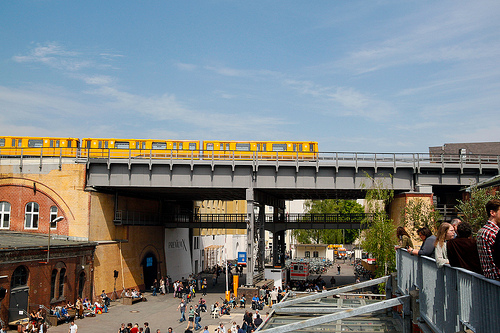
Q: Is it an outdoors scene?
A: Yes, it is outdoors.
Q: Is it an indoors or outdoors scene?
A: It is outdoors.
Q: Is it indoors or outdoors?
A: It is outdoors.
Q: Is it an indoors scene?
A: No, it is outdoors.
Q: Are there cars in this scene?
A: No, there are no cars.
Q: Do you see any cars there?
A: No, there are no cars.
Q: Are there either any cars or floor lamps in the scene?
A: No, there are no cars or floor lamps.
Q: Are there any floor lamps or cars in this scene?
A: No, there are no cars or floor lamps.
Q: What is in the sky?
A: The clouds are in the sky.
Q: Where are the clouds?
A: The clouds are in the sky.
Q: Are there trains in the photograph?
A: Yes, there is a train.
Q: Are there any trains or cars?
A: Yes, there is a train.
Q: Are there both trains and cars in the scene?
A: No, there is a train but no cars.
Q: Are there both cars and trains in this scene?
A: No, there is a train but no cars.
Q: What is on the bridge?
A: The train is on the bridge.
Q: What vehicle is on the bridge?
A: The vehicle is a train.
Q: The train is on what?
A: The train is on the bridge.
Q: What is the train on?
A: The train is on the bridge.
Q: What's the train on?
A: The train is on the bridge.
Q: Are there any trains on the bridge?
A: Yes, there is a train on the bridge.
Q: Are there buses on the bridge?
A: No, there is a train on the bridge.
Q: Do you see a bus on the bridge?
A: No, there is a train on the bridge.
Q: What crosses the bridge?
A: The train crosses the bridge.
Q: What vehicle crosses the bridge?
A: The vehicle is a train.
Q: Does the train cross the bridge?
A: Yes, the train crosses the bridge.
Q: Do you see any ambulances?
A: Yes, there is an ambulance.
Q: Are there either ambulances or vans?
A: Yes, there is an ambulance.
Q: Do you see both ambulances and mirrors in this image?
A: No, there is an ambulance but no mirrors.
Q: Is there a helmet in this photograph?
A: No, there are no helmets.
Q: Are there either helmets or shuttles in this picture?
A: No, there are no helmets or shuttles.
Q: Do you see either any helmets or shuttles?
A: No, there are no helmets or shuttles.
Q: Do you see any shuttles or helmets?
A: No, there are no helmets or shuttles.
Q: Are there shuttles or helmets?
A: No, there are no helmets or shuttles.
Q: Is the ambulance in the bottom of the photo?
A: Yes, the ambulance is in the bottom of the image.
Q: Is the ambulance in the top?
A: No, the ambulance is in the bottom of the image.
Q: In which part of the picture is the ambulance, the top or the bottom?
A: The ambulance is in the bottom of the image.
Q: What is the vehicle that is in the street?
A: The vehicle is an ambulance.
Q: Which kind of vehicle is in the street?
A: The vehicle is an ambulance.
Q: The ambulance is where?
A: The ambulance is in the street.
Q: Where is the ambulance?
A: The ambulance is in the street.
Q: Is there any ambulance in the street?
A: Yes, there is an ambulance in the street.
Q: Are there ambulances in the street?
A: Yes, there is an ambulance in the street.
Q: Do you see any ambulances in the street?
A: Yes, there is an ambulance in the street.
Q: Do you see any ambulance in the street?
A: Yes, there is an ambulance in the street.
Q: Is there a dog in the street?
A: No, there is an ambulance in the street.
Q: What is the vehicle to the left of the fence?
A: The vehicle is an ambulance.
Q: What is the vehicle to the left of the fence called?
A: The vehicle is an ambulance.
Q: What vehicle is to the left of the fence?
A: The vehicle is an ambulance.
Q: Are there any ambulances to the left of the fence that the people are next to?
A: Yes, there is an ambulance to the left of the fence.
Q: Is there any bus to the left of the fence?
A: No, there is an ambulance to the left of the fence.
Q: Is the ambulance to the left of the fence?
A: Yes, the ambulance is to the left of the fence.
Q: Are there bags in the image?
A: No, there are no bags.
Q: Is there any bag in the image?
A: No, there are no bags.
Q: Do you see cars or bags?
A: No, there are no bags or cars.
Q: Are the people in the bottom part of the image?
A: Yes, the people are in the bottom of the image.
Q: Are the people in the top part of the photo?
A: No, the people are in the bottom of the image.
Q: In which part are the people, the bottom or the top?
A: The people are in the bottom of the image.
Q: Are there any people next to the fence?
A: Yes, there are people next to the fence.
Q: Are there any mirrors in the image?
A: No, there are no mirrors.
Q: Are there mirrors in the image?
A: No, there are no mirrors.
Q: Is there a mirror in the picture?
A: No, there are no mirrors.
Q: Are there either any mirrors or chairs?
A: No, there are no mirrors or chairs.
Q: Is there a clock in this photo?
A: No, there are no clocks.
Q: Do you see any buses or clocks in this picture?
A: No, there are no clocks or buses.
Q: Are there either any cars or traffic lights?
A: No, there are no cars or traffic lights.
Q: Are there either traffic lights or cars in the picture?
A: No, there are no cars or traffic lights.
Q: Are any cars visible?
A: No, there are no cars.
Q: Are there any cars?
A: No, there are no cars.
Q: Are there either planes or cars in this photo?
A: No, there are no cars or planes.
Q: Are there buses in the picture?
A: No, there are no buses.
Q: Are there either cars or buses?
A: No, there are no buses or cars.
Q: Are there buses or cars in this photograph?
A: No, there are no buses or cars.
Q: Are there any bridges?
A: Yes, there is a bridge.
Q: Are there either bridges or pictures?
A: Yes, there is a bridge.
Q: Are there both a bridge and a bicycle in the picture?
A: No, there is a bridge but no bicycles.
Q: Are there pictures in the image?
A: No, there are no pictures.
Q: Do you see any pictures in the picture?
A: No, there are no pictures.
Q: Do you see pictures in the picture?
A: No, there are no pictures.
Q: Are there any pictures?
A: No, there are no pictures.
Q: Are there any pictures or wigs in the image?
A: No, there are no pictures or wigs.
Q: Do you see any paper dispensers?
A: No, there are no paper dispensers.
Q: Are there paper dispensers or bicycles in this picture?
A: No, there are no paper dispensers or bicycles.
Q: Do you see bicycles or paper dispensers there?
A: No, there are no paper dispensers or bicycles.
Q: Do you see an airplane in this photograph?
A: No, there are no airplanes.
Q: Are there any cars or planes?
A: No, there are no planes or cars.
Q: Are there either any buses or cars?
A: No, there are no cars or buses.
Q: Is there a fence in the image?
A: Yes, there is a fence.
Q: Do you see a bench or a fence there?
A: Yes, there is a fence.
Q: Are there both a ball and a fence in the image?
A: No, there is a fence but no balls.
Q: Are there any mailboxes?
A: No, there are no mailboxes.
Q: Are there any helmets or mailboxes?
A: No, there are no mailboxes or helmets.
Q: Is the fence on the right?
A: Yes, the fence is on the right of the image.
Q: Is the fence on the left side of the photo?
A: No, the fence is on the right of the image.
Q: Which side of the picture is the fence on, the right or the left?
A: The fence is on the right of the image.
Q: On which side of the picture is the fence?
A: The fence is on the right of the image.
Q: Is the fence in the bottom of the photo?
A: Yes, the fence is in the bottom of the image.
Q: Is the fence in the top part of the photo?
A: No, the fence is in the bottom of the image.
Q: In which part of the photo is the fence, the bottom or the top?
A: The fence is in the bottom of the image.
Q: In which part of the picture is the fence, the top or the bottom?
A: The fence is in the bottom of the image.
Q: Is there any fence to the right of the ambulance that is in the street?
A: Yes, there is a fence to the right of the ambulance.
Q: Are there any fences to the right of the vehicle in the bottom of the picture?
A: Yes, there is a fence to the right of the ambulance.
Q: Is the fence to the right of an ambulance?
A: Yes, the fence is to the right of an ambulance.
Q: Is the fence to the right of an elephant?
A: No, the fence is to the right of an ambulance.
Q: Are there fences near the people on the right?
A: Yes, there is a fence near the people.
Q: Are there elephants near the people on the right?
A: No, there is a fence near the people.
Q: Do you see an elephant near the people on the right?
A: No, there is a fence near the people.